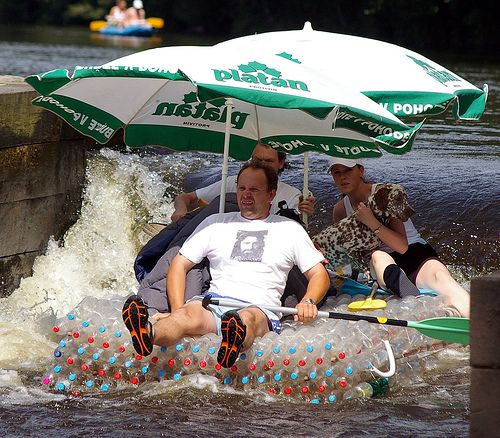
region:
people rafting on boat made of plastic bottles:
[26, 139, 483, 406]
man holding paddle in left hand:
[132, 157, 450, 371]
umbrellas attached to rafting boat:
[33, 11, 496, 248]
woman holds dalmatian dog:
[317, 157, 424, 285]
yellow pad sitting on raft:
[347, 263, 415, 321]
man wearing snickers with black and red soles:
[101, 148, 343, 395]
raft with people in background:
[81, 1, 183, 38]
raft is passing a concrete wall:
[2, 66, 137, 323]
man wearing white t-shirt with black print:
[158, 193, 335, 335]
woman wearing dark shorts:
[307, 155, 481, 325]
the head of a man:
[227, 156, 277, 221]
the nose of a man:
[237, 182, 252, 197]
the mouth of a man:
[239, 195, 255, 207]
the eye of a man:
[246, 184, 260, 194]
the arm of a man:
[293, 225, 335, 302]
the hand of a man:
[289, 293, 324, 326]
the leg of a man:
[151, 292, 219, 347]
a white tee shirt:
[176, 210, 326, 322]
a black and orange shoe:
[118, 288, 156, 359]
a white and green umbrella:
[15, 42, 430, 192]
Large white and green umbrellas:
[14, 21, 499, 148]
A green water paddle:
[187, 283, 479, 360]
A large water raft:
[41, 291, 434, 416]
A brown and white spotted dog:
[311, 169, 423, 296]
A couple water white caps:
[4, 161, 149, 322]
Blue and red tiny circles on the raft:
[71, 317, 140, 379]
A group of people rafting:
[124, 115, 479, 365]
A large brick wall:
[1, 89, 138, 345]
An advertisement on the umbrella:
[131, 74, 266, 155]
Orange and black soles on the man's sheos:
[106, 290, 318, 405]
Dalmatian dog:
[320, 175, 425, 285]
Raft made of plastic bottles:
[270, 315, 415, 400]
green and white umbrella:
[15, 35, 430, 175]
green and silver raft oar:
[200, 285, 465, 365]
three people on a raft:
[30, 115, 460, 405]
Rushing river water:
[425, 115, 475, 230]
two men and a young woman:
[110, 130, 465, 355]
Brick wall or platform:
[0, 85, 75, 275]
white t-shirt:
[195, 215, 320, 305]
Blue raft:
[70, 10, 170, 45]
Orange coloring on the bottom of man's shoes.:
[119, 298, 335, 395]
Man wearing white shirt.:
[217, 244, 291, 304]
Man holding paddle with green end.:
[236, 275, 499, 362]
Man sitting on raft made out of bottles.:
[91, 294, 400, 388]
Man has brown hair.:
[241, 154, 287, 194]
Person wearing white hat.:
[333, 150, 380, 194]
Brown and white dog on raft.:
[316, 194, 406, 303]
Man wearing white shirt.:
[283, 184, 297, 202]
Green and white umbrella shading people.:
[263, 95, 362, 224]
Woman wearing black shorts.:
[401, 243, 412, 267]